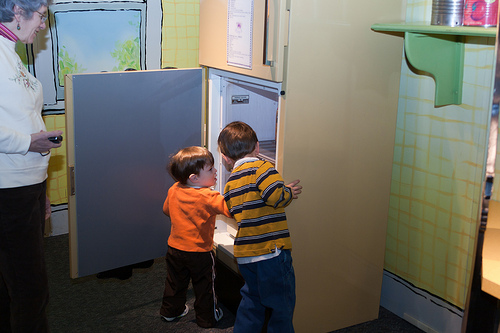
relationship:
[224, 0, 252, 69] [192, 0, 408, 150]
paper on fridge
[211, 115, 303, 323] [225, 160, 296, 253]
boy wears shirt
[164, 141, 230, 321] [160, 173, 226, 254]
boy wears shirt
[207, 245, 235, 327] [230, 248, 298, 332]
stripe on jeans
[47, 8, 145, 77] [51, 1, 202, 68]
fake window on wall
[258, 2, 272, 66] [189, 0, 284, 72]
handle on door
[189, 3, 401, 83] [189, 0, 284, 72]
fridge has door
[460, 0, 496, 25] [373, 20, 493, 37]
can on shelf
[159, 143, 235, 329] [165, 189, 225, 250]
boy wears shirt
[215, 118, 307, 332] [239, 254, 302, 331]
boy wears jeans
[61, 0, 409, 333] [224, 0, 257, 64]
fridge has paper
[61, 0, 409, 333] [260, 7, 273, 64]
fridge has handle